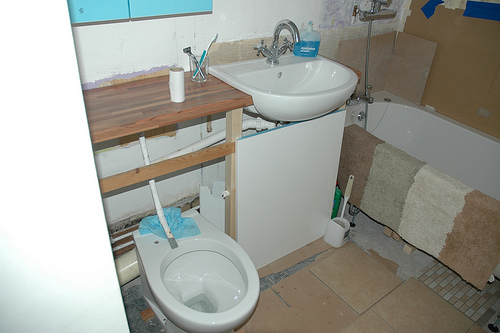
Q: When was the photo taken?
A: Daytime.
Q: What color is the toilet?
A: White.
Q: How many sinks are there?
A: One.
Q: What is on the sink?
A: A faucet.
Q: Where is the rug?
A: On the tub.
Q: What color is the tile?
A: Beige.